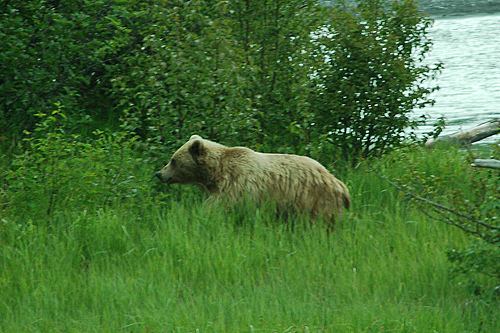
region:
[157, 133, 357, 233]
Golden colored bear.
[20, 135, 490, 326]
Bear standing in tall grass.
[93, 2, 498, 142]
Water behind green bushes.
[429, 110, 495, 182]
Tree trunks sticking out of water.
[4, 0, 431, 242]
Midsize bear in front of green bushes.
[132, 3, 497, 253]
River and bushes behind bear.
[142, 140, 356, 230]
brown bear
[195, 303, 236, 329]
long green and yellow grass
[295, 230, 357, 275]
long green and yellow grass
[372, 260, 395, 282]
long green and yellow grass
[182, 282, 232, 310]
long green and yellow grass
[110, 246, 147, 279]
long green and yellow grass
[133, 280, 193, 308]
long green and yellow grass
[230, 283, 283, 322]
long green and yellow grass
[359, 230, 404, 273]
long green and yellow grass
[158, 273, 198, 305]
long green and yellow grass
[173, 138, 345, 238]
brown bear in woods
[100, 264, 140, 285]
long green and yellow grass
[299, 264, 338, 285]
long green and yellow grass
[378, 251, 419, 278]
long green and yellow grass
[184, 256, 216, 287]
long green and yellow grass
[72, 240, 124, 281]
long green and yellow grass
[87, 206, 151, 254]
long green and yellow grass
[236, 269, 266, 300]
long green and yellow grass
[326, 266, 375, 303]
long green and yellow grass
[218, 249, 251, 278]
long green and yellow grass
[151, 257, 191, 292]
long dark green grass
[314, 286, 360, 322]
long dark green grass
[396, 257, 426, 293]
long dark green grass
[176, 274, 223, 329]
long dark green grass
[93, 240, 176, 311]
long dark green grass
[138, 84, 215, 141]
green and brown leaves in tree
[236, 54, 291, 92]
green and brown leaves in tree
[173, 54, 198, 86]
green and brown leaves in tree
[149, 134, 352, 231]
brown bear in green field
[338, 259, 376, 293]
long green and yellow grass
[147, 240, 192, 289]
long green and yellow grass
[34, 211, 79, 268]
long green and yellow grass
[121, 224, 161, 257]
long green and yellow grass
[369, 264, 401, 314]
long green and yellow grass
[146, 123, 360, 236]
a brown bear is small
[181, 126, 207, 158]
round ears of bear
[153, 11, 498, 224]
a bear near a river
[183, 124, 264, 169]
a hump on back of bear